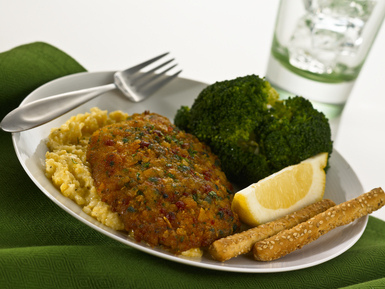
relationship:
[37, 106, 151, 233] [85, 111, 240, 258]
egg under cutlet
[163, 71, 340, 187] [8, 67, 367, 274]
broccoli in plate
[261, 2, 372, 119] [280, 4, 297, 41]
glass of water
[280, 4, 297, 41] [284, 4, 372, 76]
water with ice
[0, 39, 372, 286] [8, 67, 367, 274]
table cloth under plate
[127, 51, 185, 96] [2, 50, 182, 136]
prongs on fork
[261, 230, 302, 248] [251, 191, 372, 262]
seeds on breadstick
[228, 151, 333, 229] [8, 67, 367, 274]
lemon on plate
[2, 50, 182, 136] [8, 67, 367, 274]
fork in plate